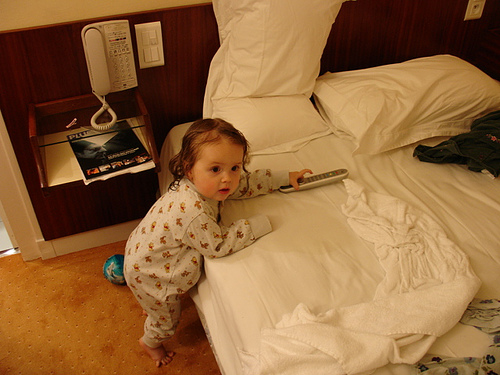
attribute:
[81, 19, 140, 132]
phone — white, old-fashioned, cordless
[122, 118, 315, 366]
girl — young, barefoot, little, holding, puzzled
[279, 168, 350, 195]
remote — gray, white, cream, silver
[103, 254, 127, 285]
ball — blue, green, tiny, white, small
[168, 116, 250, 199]
hair — brown, wet, curly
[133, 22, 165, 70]
light switches — white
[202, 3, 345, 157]
pillow — white, firm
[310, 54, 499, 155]
pillow — white, firm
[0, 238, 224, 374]
carpet — light brown, orange, off-putting, brown, patterned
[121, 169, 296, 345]
jumper — winnie-the-pooh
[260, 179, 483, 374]
towel — white, wadded up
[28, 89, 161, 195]
shelf — mounted, small, brown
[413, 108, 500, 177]
clothing — dark gray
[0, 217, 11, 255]
floor — white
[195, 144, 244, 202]
face — tiny